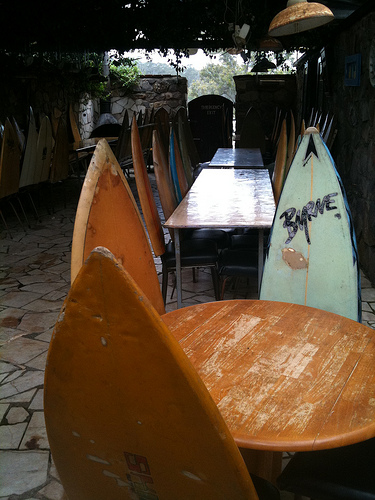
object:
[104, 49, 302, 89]
grey sky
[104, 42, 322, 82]
outside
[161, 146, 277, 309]
dining table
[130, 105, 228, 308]
chairs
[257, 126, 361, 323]
board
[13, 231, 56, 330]
onions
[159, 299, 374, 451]
table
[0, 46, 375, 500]
room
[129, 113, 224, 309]
seats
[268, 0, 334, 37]
lamp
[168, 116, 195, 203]
board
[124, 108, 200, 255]
surf boards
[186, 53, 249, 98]
green trees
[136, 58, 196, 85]
green trees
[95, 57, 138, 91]
green trees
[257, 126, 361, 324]
surfboard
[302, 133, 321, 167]
emblem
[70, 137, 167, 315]
backrests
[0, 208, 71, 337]
stones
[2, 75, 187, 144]
stone wall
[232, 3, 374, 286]
stone wall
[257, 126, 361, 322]
dining chair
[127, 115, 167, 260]
surfboard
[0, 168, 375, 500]
ground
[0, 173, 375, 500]
floor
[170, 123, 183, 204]
border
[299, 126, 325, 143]
tip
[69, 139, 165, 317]
surfboard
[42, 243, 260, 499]
surfboard